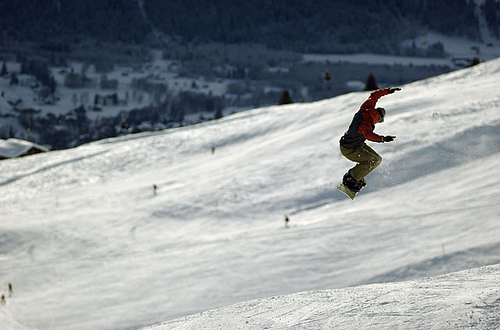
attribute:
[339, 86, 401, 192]
person — here, snowboarder, jumping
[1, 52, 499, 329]
snow — white, snowy, here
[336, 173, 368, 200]
snowboard — white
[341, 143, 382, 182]
pants — brown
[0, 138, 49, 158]
roof — snowy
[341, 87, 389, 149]
jacket — red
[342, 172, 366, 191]
shoes — black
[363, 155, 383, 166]
knees — bent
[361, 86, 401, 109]
arm — extended